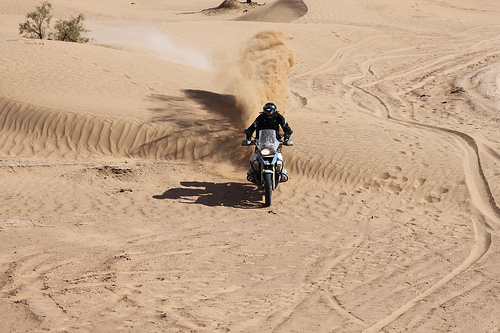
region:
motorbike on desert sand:
[224, 96, 307, 215]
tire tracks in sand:
[435, 118, 486, 177]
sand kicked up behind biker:
[233, 27, 298, 117]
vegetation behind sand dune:
[20, 5, 95, 47]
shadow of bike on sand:
[152, 168, 264, 214]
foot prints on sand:
[358, 161, 440, 219]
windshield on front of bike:
[252, 123, 283, 158]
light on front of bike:
[255, 141, 275, 161]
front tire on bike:
[258, 167, 280, 216]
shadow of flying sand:
[180, 85, 235, 127]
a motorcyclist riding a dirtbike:
[211, 83, 316, 209]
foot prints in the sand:
[337, 118, 460, 256]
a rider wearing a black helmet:
[218, 97, 307, 212]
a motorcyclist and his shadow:
[143, 91, 314, 226]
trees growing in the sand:
[7, 0, 117, 52]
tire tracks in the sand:
[279, 223, 485, 318]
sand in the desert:
[103, 228, 355, 311]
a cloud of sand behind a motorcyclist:
[206, 21, 319, 216]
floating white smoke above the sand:
[76, 14, 213, 81]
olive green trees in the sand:
[7, 1, 91, 51]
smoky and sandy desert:
[239, 29, 299, 104]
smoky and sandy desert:
[194, 28, 291, 114]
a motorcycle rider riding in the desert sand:
[242, 101, 294, 207]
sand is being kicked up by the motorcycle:
[206, 25, 295, 100]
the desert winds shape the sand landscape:
[0, 107, 241, 170]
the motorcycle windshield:
[258, 126, 278, 148]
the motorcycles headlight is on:
[260, 147, 272, 157]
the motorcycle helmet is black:
[262, 101, 277, 118]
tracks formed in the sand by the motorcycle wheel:
[351, 30, 498, 331]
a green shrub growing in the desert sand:
[18, 0, 93, 42]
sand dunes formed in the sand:
[2, 37, 228, 329]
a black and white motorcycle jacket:
[243, 112, 293, 142]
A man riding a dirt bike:
[228, 95, 305, 200]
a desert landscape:
[8, 5, 493, 331]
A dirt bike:
[243, 128, 296, 200]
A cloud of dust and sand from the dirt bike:
[227, 23, 295, 148]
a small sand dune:
[0, 24, 312, 195]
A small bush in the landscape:
[16, 0, 96, 45]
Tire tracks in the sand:
[0, 35, 499, 330]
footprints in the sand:
[102, 135, 439, 322]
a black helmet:
[259, 99, 279, 116]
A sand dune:
[236, 0, 343, 17]